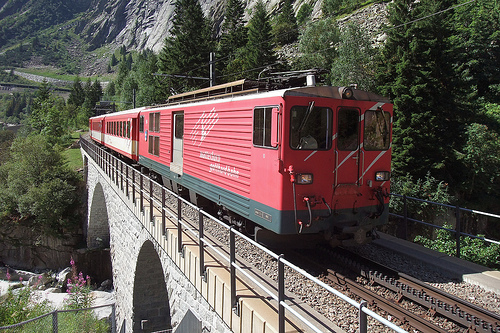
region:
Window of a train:
[285, 99, 332, 156]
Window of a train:
[333, 99, 360, 159]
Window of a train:
[361, 108, 388, 157]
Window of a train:
[263, 106, 283, 151]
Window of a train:
[250, 102, 263, 152]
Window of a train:
[170, 111, 187, 142]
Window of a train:
[153, 111, 160, 132]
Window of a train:
[152, 136, 159, 160]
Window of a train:
[148, 136, 153, 157]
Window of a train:
[146, 108, 153, 130]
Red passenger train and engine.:
[83, 71, 396, 242]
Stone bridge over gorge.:
[2, 128, 491, 329]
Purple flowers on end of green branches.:
[63, 257, 98, 289]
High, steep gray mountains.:
[5, 1, 360, 68]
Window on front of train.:
[285, 101, 330, 146]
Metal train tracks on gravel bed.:
[335, 243, 455, 325]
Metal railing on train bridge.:
[71, 125, 339, 328]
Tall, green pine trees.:
[140, 3, 495, 128]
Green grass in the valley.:
[10, 60, 96, 173]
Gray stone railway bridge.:
[79, 151, 288, 325]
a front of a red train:
[279, 88, 394, 245]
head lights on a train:
[286, 168, 396, 188]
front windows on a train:
[289, 103, 388, 150]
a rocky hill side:
[104, 0, 167, 54]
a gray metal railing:
[121, 170, 215, 260]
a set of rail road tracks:
[319, 245, 496, 332]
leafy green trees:
[408, 1, 499, 173]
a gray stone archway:
[117, 231, 178, 328]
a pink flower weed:
[69, 257, 91, 304]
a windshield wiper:
[296, 102, 321, 153]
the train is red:
[14, 56, 386, 213]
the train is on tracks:
[290, 205, 447, 305]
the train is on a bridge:
[52, 113, 264, 248]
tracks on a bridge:
[15, 141, 299, 241]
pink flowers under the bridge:
[50, 238, 115, 312]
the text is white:
[175, 100, 256, 172]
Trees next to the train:
[369, 15, 499, 180]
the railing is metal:
[94, 140, 375, 320]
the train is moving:
[55, 93, 401, 212]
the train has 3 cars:
[22, 73, 417, 216]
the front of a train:
[284, 79, 396, 226]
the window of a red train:
[284, 99, 396, 159]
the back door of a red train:
[327, 97, 364, 192]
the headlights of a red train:
[289, 167, 316, 187]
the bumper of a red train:
[301, 193, 384, 243]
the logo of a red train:
[187, 107, 234, 177]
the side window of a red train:
[244, 103, 286, 160]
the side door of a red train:
[167, 107, 191, 171]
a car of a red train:
[101, 107, 148, 158]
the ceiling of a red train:
[182, 70, 271, 104]